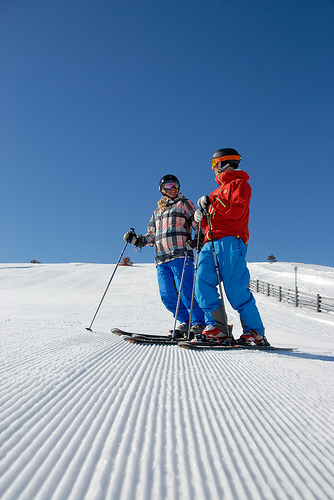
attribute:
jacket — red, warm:
[199, 169, 254, 245]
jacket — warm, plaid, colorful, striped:
[131, 193, 199, 266]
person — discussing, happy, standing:
[191, 145, 267, 348]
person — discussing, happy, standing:
[123, 175, 202, 339]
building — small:
[30, 259, 40, 266]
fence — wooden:
[247, 274, 333, 317]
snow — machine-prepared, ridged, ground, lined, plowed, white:
[0, 258, 332, 498]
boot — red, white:
[198, 323, 228, 341]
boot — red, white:
[238, 326, 270, 347]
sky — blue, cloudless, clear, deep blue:
[0, 0, 334, 268]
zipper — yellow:
[206, 175, 224, 241]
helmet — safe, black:
[209, 146, 243, 171]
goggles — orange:
[208, 155, 242, 169]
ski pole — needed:
[186, 216, 201, 343]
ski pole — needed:
[202, 207, 234, 348]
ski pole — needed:
[171, 239, 191, 342]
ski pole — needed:
[87, 227, 134, 332]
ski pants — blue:
[193, 236, 266, 339]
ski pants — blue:
[154, 253, 201, 328]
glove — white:
[195, 195, 208, 210]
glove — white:
[193, 208, 203, 224]